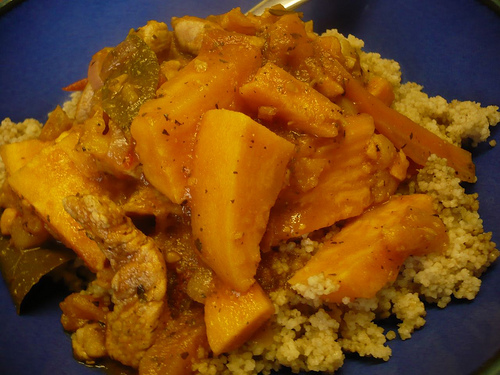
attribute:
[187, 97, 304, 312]
vegetable — cooked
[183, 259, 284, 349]
vegetable — cooked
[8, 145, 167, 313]
vegetable — cooked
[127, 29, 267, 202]
vegetable — cooked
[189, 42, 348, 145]
vegetable — cooked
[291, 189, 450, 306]
food — orange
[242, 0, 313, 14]
handle — silver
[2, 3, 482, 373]
plate — blue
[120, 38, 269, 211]
vegetable — cooked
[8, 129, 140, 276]
vegetable — cooked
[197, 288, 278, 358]
vegetable — cooked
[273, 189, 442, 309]
vegetable — cooked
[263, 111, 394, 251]
vegetable — cooked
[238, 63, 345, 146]
vegetable — cooked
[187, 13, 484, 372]
food — cooked